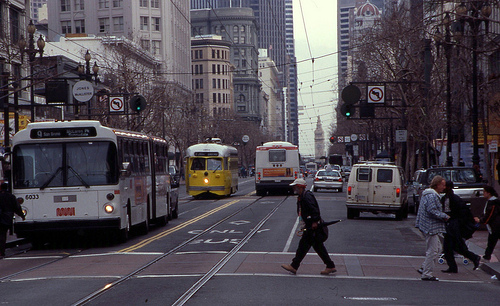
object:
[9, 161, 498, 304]
road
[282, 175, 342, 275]
man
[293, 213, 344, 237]
umbrella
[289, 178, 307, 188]
cap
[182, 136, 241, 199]
streetcar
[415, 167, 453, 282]
man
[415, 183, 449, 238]
shirt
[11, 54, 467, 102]
power line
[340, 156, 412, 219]
van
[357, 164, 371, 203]
ladder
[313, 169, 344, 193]
cab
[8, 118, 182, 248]
bus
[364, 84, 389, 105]
sign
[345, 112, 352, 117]
light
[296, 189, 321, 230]
jacket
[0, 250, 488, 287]
crosswalk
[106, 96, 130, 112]
sign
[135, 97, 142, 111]
light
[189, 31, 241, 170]
building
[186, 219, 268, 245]
words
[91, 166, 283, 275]
line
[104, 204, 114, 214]
light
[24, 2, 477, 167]
power line